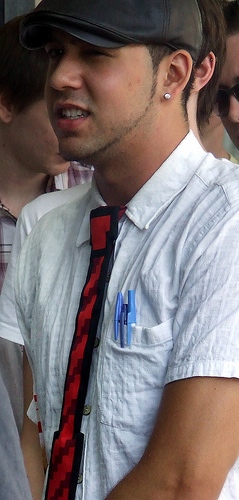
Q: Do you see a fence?
A: No, there are no fences.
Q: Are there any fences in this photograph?
A: No, there are no fences.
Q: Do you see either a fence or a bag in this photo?
A: No, there are no fences or bags.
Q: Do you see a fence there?
A: No, there are no fences.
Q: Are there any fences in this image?
A: No, there are no fences.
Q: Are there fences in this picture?
A: No, there are no fences.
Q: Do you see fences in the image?
A: No, there are no fences.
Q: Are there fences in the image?
A: No, there are no fences.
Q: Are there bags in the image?
A: No, there are no bags.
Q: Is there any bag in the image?
A: No, there are no bags.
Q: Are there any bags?
A: No, there are no bags.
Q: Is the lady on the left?
A: Yes, the lady is on the left of the image.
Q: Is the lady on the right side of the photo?
A: No, the lady is on the left of the image.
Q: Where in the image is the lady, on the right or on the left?
A: The lady is on the left of the image.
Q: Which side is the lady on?
A: The lady is on the left of the image.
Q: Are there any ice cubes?
A: No, there are no ice cubes.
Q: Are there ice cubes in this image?
A: No, there are no ice cubes.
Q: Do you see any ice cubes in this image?
A: No, there are no ice cubes.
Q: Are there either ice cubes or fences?
A: No, there are no ice cubes or fences.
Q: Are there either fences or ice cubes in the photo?
A: No, there are no ice cubes or fences.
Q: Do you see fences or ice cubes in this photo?
A: No, there are no ice cubes or fences.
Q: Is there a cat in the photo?
A: No, there are no cats.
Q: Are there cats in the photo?
A: No, there are no cats.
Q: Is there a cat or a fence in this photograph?
A: No, there are no cats or fences.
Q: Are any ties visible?
A: Yes, there is a tie.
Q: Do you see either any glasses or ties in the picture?
A: Yes, there is a tie.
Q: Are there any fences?
A: No, there are no fences.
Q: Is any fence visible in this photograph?
A: No, there are no fences.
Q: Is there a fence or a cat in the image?
A: No, there are no fences or cats.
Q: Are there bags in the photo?
A: No, there are no bags.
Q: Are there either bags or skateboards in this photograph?
A: No, there are no bags or skateboards.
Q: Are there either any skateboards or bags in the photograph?
A: No, there are no bags or skateboards.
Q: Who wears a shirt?
A: The guy wears a shirt.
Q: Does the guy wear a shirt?
A: Yes, the guy wears a shirt.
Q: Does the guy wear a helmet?
A: No, the guy wears a shirt.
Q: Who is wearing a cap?
A: The guy is wearing a cap.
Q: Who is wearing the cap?
A: The guy is wearing a cap.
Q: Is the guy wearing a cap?
A: Yes, the guy is wearing a cap.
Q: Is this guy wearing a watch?
A: No, the guy is wearing a cap.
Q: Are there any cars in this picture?
A: No, there are no cars.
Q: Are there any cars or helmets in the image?
A: No, there are no cars or helmets.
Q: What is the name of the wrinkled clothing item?
A: The clothing item is a shirt.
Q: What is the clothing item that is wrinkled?
A: The clothing item is a shirt.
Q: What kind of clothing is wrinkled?
A: The clothing is a shirt.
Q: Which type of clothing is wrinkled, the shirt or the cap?
A: The shirt is wrinkled.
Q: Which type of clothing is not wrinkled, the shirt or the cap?
A: The cap is not wrinkled.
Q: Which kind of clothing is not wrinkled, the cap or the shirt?
A: The cap is not wrinkled.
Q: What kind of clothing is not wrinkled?
A: The clothing is a cap.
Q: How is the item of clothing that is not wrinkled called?
A: The clothing item is a cap.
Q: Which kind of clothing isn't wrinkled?
A: The clothing is a cap.